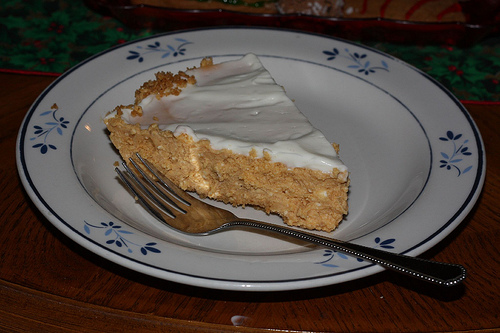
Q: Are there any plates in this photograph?
A: Yes, there is a plate.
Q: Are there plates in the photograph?
A: Yes, there is a plate.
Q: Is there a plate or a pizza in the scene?
A: Yes, there is a plate.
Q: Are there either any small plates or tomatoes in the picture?
A: Yes, there is a small plate.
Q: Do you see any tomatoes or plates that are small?
A: Yes, the plate is small.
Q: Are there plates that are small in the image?
A: Yes, there is a small plate.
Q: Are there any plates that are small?
A: Yes, there is a plate that is small.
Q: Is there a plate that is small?
A: Yes, there is a plate that is small.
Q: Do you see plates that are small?
A: Yes, there is a plate that is small.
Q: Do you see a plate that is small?
A: Yes, there is a plate that is small.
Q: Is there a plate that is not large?
A: Yes, there is a small plate.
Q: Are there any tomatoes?
A: No, there are no tomatoes.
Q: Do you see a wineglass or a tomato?
A: No, there are no tomatoes or wine glasses.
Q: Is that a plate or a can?
A: That is a plate.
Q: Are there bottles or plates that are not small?
A: No, there is a plate but it is small.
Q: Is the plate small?
A: Yes, the plate is small.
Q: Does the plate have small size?
A: Yes, the plate is small.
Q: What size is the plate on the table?
A: The plate is small.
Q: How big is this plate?
A: The plate is small.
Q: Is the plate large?
A: No, the plate is small.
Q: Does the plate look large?
A: No, the plate is small.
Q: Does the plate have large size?
A: No, the plate is small.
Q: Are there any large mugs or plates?
A: No, there is a plate but it is small.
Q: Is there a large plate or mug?
A: No, there is a plate but it is small.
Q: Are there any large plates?
A: No, there is a plate but it is small.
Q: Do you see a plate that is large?
A: No, there is a plate but it is small.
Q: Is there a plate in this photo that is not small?
A: No, there is a plate but it is small.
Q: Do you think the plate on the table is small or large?
A: The plate is small.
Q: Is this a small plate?
A: Yes, this is a small plate.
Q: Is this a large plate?
A: No, this is a small plate.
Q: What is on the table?
A: The plate is on the table.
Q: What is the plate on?
A: The plate is on the table.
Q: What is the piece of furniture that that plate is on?
A: The piece of furniture is a table.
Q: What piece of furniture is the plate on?
A: The plate is on the table.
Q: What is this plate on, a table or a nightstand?
A: The plate is on a table.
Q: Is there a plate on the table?
A: Yes, there is a plate on the table.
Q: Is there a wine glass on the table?
A: No, there is a plate on the table.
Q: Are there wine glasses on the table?
A: No, there is a plate on the table.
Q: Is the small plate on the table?
A: Yes, the plate is on the table.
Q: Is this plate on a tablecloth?
A: No, the plate is on the table.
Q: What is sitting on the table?
A: The plate is sitting on the table.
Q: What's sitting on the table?
A: The plate is sitting on the table.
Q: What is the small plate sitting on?
A: The plate is sitting on the table.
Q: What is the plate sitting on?
A: The plate is sitting on the table.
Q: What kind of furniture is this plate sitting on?
A: The plate is sitting on the table.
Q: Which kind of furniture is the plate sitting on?
A: The plate is sitting on the table.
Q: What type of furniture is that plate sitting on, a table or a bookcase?
A: The plate is sitting on a table.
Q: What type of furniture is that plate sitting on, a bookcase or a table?
A: The plate is sitting on a table.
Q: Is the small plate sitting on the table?
A: Yes, the plate is sitting on the table.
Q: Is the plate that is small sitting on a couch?
A: No, the plate is sitting on the table.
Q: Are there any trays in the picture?
A: No, there are no trays.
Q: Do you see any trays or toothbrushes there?
A: No, there are no trays or toothbrushes.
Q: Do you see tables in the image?
A: Yes, there is a table.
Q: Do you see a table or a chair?
A: Yes, there is a table.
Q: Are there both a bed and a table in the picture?
A: No, there is a table but no beds.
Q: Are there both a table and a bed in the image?
A: No, there is a table but no beds.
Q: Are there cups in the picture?
A: No, there are no cups.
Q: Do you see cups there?
A: No, there are no cups.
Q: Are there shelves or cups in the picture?
A: No, there are no cups or shelves.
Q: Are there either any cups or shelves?
A: No, there are no cups or shelves.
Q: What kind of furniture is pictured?
A: The furniture is a table.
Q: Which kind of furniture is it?
A: The piece of furniture is a table.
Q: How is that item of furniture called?
A: This is a table.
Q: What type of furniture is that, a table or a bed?
A: This is a table.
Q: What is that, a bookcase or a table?
A: That is a table.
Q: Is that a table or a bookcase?
A: That is a table.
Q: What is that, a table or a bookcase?
A: That is a table.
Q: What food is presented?
A: The food is a pie.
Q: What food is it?
A: The food is a pie.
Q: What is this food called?
A: This is a pie.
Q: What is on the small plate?
A: The pie is on the plate.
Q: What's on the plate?
A: The pie is on the plate.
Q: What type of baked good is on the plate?
A: The food is a pie.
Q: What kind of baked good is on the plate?
A: The food is a pie.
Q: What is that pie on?
A: The pie is on the plate.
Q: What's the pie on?
A: The pie is on the plate.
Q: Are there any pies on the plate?
A: Yes, there is a pie on the plate.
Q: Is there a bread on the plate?
A: No, there is a pie on the plate.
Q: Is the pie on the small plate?
A: Yes, the pie is on the plate.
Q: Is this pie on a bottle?
A: No, the pie is on the plate.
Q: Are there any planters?
A: No, there are no planters.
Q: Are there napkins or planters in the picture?
A: No, there are no planters or napkins.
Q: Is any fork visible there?
A: Yes, there is a fork.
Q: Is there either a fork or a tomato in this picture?
A: Yes, there is a fork.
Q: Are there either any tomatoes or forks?
A: Yes, there is a fork.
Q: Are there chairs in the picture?
A: No, there are no chairs.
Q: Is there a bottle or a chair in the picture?
A: No, there are no chairs or bottles.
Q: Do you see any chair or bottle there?
A: No, there are no chairs or bottles.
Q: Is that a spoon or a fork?
A: That is a fork.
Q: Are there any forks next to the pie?
A: Yes, there is a fork next to the pie.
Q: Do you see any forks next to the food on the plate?
A: Yes, there is a fork next to the pie.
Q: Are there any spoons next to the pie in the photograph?
A: No, there is a fork next to the pie.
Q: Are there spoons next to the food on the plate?
A: No, there is a fork next to the pie.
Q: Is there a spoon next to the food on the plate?
A: No, there is a fork next to the pie.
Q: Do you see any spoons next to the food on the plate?
A: No, there is a fork next to the pie.